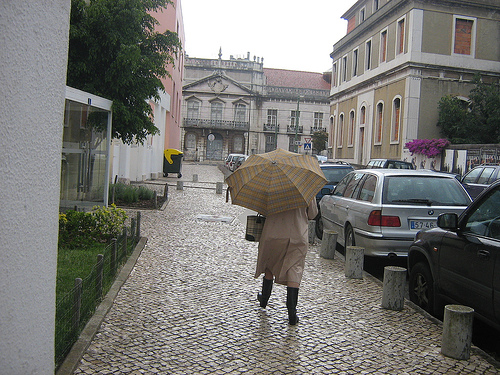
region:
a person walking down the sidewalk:
[216, 122, 326, 339]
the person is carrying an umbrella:
[225, 152, 328, 220]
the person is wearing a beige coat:
[255, 186, 307, 293]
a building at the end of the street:
[181, 37, 337, 171]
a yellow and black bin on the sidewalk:
[164, 147, 184, 175]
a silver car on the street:
[315, 164, 474, 256]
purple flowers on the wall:
[407, 133, 444, 155]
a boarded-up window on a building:
[451, 12, 476, 58]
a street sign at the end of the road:
[298, 134, 315, 155]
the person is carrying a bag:
[238, 205, 266, 242]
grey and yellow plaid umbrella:
[228, 150, 328, 213]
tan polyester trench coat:
[256, 196, 318, 289]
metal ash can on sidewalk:
[379, 265, 406, 310]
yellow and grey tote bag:
[245, 215, 263, 240]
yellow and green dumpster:
[166, 148, 184, 178]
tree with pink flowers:
[407, 136, 448, 155]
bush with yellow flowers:
[63, 204, 125, 239]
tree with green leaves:
[71, 1, 182, 143]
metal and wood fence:
[61, 210, 143, 360]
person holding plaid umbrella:
[231, 145, 323, 323]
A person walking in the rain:
[205, 134, 338, 331]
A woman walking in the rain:
[200, 139, 340, 331]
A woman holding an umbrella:
[216, 142, 329, 329]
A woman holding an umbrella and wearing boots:
[213, 135, 319, 340]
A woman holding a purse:
[237, 188, 277, 250]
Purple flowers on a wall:
[402, 128, 456, 160]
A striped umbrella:
[223, 142, 329, 216]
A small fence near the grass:
[57, 207, 147, 349]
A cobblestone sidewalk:
[174, 189, 236, 359]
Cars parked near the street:
[296, 167, 497, 325]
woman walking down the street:
[218, 135, 336, 325]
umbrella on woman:
[235, 148, 318, 214]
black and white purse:
[240, 206, 267, 243]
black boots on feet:
[246, 278, 325, 326]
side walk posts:
[328, 246, 408, 313]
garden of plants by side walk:
[57, 206, 143, 278]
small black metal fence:
[77, 221, 134, 313]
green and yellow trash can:
[160, 150, 186, 177]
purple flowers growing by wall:
[406, 135, 444, 156]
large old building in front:
[183, 35, 329, 161]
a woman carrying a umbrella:
[223, 119, 339, 326]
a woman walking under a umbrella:
[210, 130, 333, 348]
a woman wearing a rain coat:
[258, 141, 328, 307]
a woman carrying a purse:
[222, 169, 284, 272]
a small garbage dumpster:
[158, 139, 183, 196]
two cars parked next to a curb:
[321, 178, 498, 283]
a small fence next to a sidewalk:
[65, 214, 145, 339]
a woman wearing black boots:
[262, 141, 324, 335]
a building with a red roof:
[252, 65, 322, 132]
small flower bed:
[92, 179, 172, 221]